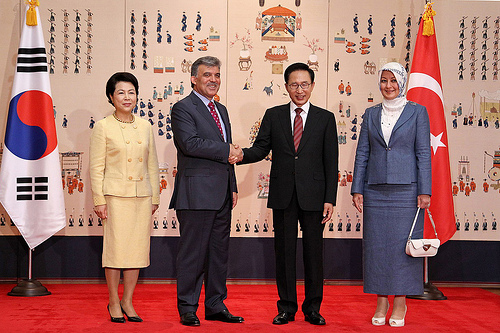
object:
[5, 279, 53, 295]
bottom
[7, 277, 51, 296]
holder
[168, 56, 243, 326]
man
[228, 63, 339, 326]
man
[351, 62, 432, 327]
woman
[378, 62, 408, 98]
head scarf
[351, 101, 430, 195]
jacket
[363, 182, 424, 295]
skirt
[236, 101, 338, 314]
suit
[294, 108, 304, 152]
tie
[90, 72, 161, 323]
woman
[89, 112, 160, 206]
jacket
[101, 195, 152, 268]
skirt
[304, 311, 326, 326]
shoe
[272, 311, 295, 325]
shoe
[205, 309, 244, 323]
shoe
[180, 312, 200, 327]
shoe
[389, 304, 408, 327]
shoe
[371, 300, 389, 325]
shoe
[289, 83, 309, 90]
glasses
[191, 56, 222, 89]
hair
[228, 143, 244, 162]
hand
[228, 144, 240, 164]
hand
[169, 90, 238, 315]
suit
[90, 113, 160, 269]
outfit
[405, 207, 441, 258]
purse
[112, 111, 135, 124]
necklace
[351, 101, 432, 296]
outfit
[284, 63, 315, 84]
hair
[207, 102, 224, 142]
tie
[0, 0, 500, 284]
wall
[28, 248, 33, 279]
flag pole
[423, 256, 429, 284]
flag pole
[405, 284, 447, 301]
stand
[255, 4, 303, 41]
drawing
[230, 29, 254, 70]
drawing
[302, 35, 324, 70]
drawing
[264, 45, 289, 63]
drawing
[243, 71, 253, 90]
drawing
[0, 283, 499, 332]
carpet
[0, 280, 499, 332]
floor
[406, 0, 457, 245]
flag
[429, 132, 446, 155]
star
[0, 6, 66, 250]
flag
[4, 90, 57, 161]
circle